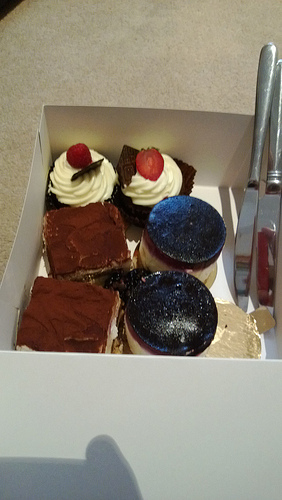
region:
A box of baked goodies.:
[0, 96, 280, 372]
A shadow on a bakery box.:
[3, 423, 168, 498]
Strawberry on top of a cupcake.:
[66, 143, 92, 169]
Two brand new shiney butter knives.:
[233, 46, 280, 313]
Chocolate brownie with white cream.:
[115, 143, 195, 195]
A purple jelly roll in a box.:
[145, 194, 227, 266]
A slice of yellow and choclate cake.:
[42, 202, 132, 275]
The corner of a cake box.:
[38, 101, 102, 137]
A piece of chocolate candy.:
[67, 161, 114, 182]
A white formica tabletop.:
[26, 9, 240, 100]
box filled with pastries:
[0, 103, 279, 499]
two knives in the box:
[234, 42, 280, 325]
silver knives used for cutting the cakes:
[233, 42, 281, 323]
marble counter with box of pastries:
[0, 0, 281, 282]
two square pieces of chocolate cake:
[18, 202, 127, 355]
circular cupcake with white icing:
[48, 142, 114, 205]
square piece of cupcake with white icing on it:
[111, 144, 196, 226]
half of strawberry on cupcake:
[138, 149, 163, 180]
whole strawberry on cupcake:
[65, 142, 90, 166]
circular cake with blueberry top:
[134, 196, 226, 281]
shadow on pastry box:
[0, 431, 169, 499]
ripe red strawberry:
[137, 143, 164, 181]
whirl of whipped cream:
[53, 150, 115, 203]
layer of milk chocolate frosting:
[44, 208, 129, 270]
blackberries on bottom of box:
[82, 262, 148, 306]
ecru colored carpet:
[0, 0, 281, 150]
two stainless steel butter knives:
[232, 40, 281, 316]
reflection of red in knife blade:
[254, 221, 272, 315]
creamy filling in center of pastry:
[136, 241, 220, 288]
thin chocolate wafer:
[72, 157, 105, 181]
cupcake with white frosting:
[48, 133, 117, 202]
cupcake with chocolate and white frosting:
[111, 142, 195, 212]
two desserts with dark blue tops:
[125, 197, 225, 348]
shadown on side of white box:
[6, 425, 128, 499]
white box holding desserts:
[6, 91, 271, 497]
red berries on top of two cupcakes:
[63, 140, 168, 177]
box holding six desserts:
[13, 94, 281, 387]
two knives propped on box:
[232, 33, 281, 326]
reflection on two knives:
[232, 216, 280, 303]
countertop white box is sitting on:
[2, 4, 259, 445]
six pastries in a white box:
[6, 103, 233, 356]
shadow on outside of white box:
[3, 431, 143, 498]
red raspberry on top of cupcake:
[66, 141, 92, 168]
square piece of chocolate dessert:
[16, 275, 124, 352]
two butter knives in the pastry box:
[232, 42, 280, 317]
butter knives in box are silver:
[231, 43, 278, 304]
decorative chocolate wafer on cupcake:
[70, 158, 102, 180]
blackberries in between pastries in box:
[106, 266, 152, 298]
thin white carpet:
[4, 19, 228, 96]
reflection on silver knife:
[254, 221, 278, 312]